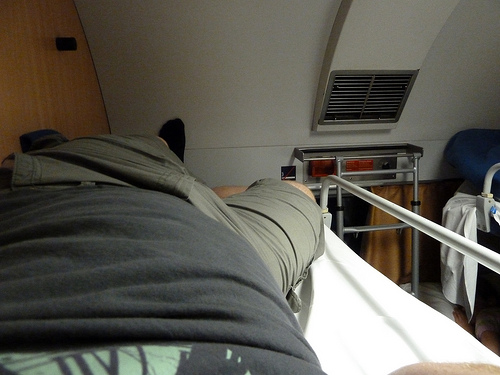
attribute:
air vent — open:
[317, 61, 411, 127]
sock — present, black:
[156, 120, 181, 158]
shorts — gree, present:
[8, 118, 330, 287]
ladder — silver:
[298, 137, 429, 287]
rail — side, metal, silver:
[303, 166, 499, 333]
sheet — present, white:
[232, 202, 495, 372]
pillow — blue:
[437, 118, 499, 178]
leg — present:
[206, 169, 325, 277]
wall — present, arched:
[80, 5, 489, 185]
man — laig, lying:
[1, 115, 350, 374]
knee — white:
[285, 175, 308, 197]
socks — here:
[140, 114, 252, 185]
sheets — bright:
[197, 159, 409, 329]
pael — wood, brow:
[2, 3, 118, 133]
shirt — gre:
[12, 182, 295, 373]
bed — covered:
[38, 114, 431, 278]